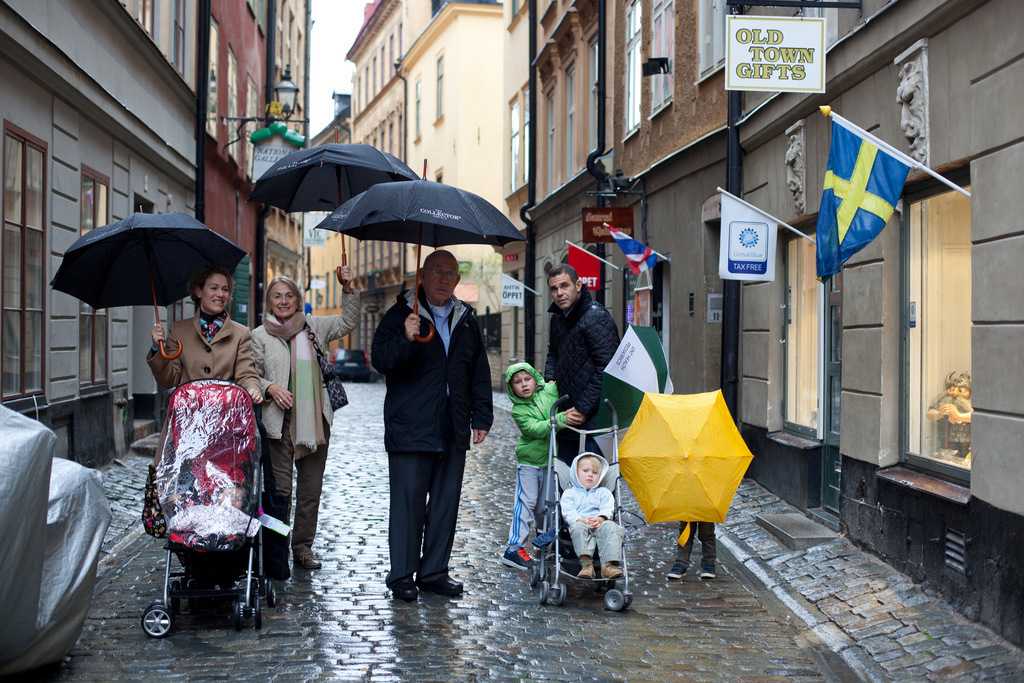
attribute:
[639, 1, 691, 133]
window — glass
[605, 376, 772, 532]
umbrella — yellow